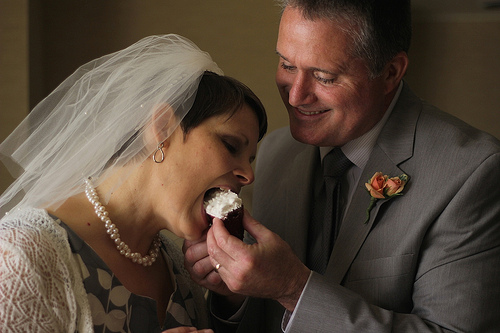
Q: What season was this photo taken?
A: Spring.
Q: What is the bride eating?
A: Cake.